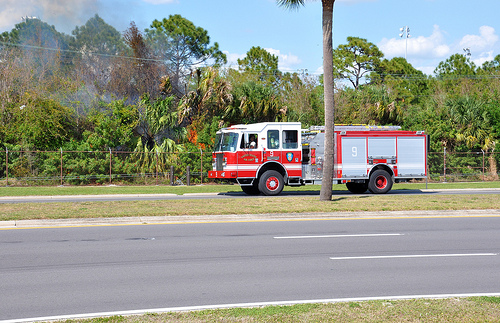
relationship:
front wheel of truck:
[258, 166, 285, 198] [202, 118, 433, 195]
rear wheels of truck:
[351, 174, 397, 196] [202, 118, 433, 195]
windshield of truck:
[210, 133, 235, 148] [202, 118, 433, 195]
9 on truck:
[351, 147, 357, 157] [203, 114, 432, 201]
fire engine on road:
[207, 116, 432, 188] [0, 187, 499, 204]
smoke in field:
[11, 10, 141, 61] [1, 14, 218, 184]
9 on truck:
[264, 148, 277, 158] [203, 114, 432, 201]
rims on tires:
[252, 166, 310, 198] [219, 156, 306, 216]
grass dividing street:
[7, 187, 494, 221] [1, 189, 499, 321]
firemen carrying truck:
[229, 133, 295, 148] [202, 118, 433, 195]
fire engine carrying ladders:
[207, 122, 429, 197] [271, 115, 412, 143]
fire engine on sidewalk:
[207, 122, 429, 197] [2, 186, 498, 201]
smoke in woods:
[0, 0, 182, 115] [0, 13, 500, 184]